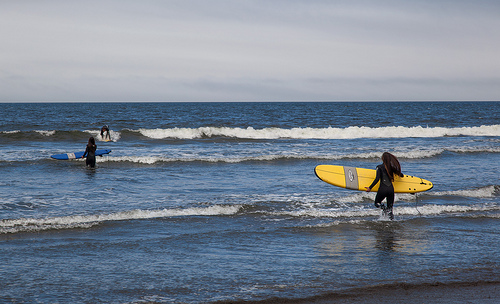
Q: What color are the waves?
A: White.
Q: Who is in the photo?
A: Surfers.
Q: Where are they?
A: The ocean.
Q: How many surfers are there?
A: Three.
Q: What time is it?
A: Daytime.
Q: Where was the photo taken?
A: At a beach.